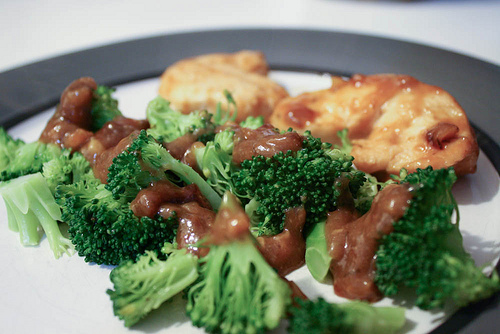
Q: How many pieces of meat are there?
A: Two.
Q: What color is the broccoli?
A: Green.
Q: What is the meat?
A: Chicken.